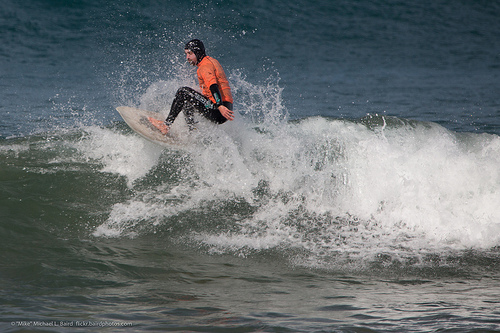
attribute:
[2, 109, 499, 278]
wave — white, blue, gray, rolling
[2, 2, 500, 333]
ocean — wet, copyrighted, splashing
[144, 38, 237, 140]
man — young, surfing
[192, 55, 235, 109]
shirt — orange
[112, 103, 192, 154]
surfboard — white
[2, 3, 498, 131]
water — gray blue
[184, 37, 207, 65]
hat — black, tight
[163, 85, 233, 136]
pants — black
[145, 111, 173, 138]
foot — bare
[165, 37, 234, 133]
wet suit — black